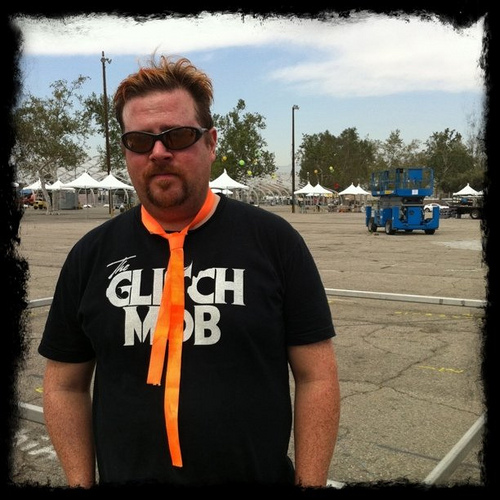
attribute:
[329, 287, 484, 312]
line — white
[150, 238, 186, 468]
tie — orange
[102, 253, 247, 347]
text — white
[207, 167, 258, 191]
tent top — white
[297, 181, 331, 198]
umbrella — open, white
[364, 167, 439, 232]
vehicle — blue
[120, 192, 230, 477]
tie — orange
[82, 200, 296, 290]
shirt — black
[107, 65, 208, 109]
hair — blonde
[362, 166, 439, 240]
vehicle — blue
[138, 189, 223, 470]
ribbon — orange